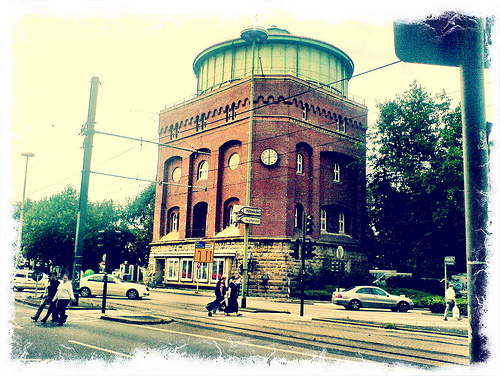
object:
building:
[143, 23, 369, 299]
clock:
[259, 147, 279, 168]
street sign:
[232, 204, 263, 225]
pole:
[241, 223, 249, 308]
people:
[31, 272, 60, 322]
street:
[12, 290, 472, 362]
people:
[205, 275, 229, 317]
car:
[331, 285, 415, 312]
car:
[77, 273, 152, 299]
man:
[443, 284, 463, 321]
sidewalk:
[313, 312, 467, 336]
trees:
[13, 79, 464, 287]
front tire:
[397, 301, 410, 313]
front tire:
[127, 288, 139, 299]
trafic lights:
[288, 215, 317, 261]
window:
[356, 287, 387, 296]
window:
[87, 275, 116, 283]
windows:
[294, 152, 346, 236]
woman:
[52, 274, 77, 327]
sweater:
[52, 282, 76, 302]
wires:
[13, 60, 493, 203]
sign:
[193, 241, 214, 263]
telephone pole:
[71, 75, 100, 306]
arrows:
[197, 250, 212, 261]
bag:
[452, 304, 460, 319]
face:
[261, 149, 279, 166]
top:
[191, 24, 355, 99]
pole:
[300, 211, 306, 316]